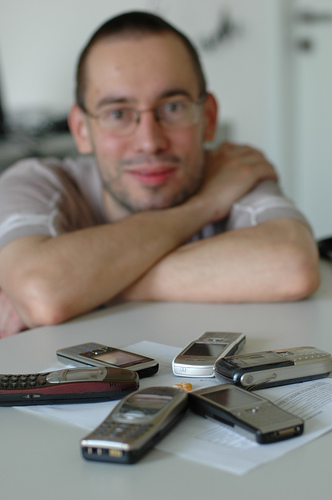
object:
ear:
[198, 90, 220, 147]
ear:
[65, 101, 94, 157]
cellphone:
[169, 325, 251, 380]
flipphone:
[211, 343, 332, 394]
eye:
[101, 102, 137, 132]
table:
[10, 423, 60, 475]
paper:
[155, 444, 256, 480]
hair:
[70, 8, 207, 113]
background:
[0, 0, 331, 232]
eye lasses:
[71, 89, 211, 134]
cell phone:
[78, 381, 190, 468]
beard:
[100, 154, 199, 210]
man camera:
[0, 10, 325, 335]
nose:
[134, 127, 170, 156]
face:
[88, 44, 194, 211]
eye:
[163, 98, 188, 117]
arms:
[0, 139, 281, 331]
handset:
[187, 381, 304, 443]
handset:
[170, 327, 245, 377]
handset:
[0, 364, 140, 403]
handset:
[52, 340, 161, 382]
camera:
[0, 363, 141, 408]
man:
[0, 6, 322, 340]